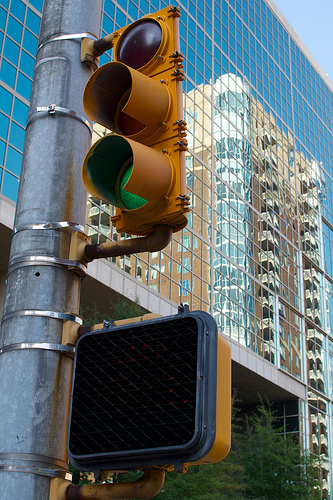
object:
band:
[0, 299, 82, 352]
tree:
[69, 293, 328, 498]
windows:
[194, 57, 330, 316]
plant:
[238, 396, 330, 499]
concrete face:
[82, 246, 329, 401]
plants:
[239, 391, 287, 499]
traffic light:
[80, 3, 188, 261]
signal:
[80, 25, 182, 237]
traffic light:
[81, 133, 174, 213]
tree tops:
[123, 383, 323, 498]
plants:
[290, 445, 328, 498]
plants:
[166, 472, 203, 499]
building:
[0, 0, 332, 499]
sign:
[74, 318, 234, 460]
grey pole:
[46, 6, 67, 216]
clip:
[1, 308, 85, 327]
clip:
[4, 255, 88, 274]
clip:
[0, 464, 72, 480]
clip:
[25, 105, 92, 136]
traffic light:
[81, 61, 172, 143]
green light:
[78, 132, 173, 214]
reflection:
[177, 65, 330, 495]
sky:
[276, 2, 331, 66]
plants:
[219, 379, 244, 499]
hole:
[34, 270, 41, 278]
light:
[115, 10, 164, 71]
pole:
[0, 0, 106, 500]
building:
[70, 305, 232, 474]